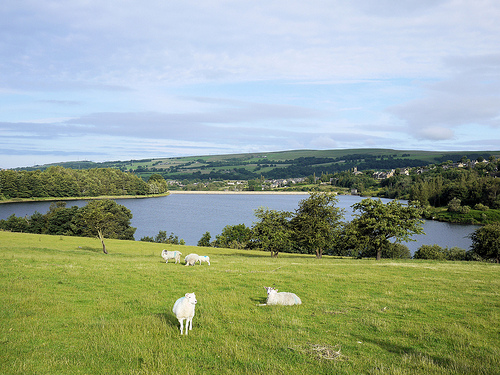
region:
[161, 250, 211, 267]
Sheep on a pasture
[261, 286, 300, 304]
A sheep lying on the grass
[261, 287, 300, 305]
A white sheep on the grass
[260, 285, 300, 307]
A sheep lying on its own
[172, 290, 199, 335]
A sheep standing alone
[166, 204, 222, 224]
A lake with blue water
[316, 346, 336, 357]
Dry grass on the pasture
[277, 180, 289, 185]
Buildings in the background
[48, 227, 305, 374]
sheep on a grassy field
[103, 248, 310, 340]
sheep on a field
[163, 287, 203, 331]
sheep standing on grass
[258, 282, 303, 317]
sheep laying on grass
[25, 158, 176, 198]
trees in back of water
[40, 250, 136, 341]
large grassy field in front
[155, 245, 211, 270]
three sheep walking in back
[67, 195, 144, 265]
small tree with leaves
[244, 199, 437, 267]
three trees lined up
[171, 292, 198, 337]
a white sheep in the field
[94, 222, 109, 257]
a dead tree in the field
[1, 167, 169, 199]
a thick forest along the shoreline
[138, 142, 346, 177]
hilly terrain across the lake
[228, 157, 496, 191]
a small town across the lake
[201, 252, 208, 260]
blue paint on the back of the sheep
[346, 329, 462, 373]
a shadow on the ground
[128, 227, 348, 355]
some sheep in a field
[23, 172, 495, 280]
a pretty body of water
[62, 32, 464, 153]
white clouds in the sky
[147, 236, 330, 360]
white sheep on a hill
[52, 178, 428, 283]
trees behind the sheep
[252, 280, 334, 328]
one sheep is laying down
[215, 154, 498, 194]
many houses in the distance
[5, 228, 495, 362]
grass covers the ground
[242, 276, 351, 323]
a sheep laying in the grass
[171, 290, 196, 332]
lamb standing around doing nothing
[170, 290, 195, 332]
the lamb is white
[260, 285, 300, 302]
lamb is lying down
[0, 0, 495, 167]
thin clouds in sky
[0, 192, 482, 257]
lake in the background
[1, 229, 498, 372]
short and green grass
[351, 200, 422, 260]
there's a tree in the distance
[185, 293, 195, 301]
head of a lamb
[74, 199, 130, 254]
tree is slightly bent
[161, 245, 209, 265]
a group of lambs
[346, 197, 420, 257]
A tree in a field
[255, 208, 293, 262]
A tree in a field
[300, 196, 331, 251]
A tree in a field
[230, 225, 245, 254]
A tree in a field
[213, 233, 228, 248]
A tree in a field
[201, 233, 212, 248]
A tree in a field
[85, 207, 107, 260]
A tree in a field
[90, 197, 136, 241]
A tree in a field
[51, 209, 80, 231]
A tree in a field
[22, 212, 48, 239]
A tree in a field